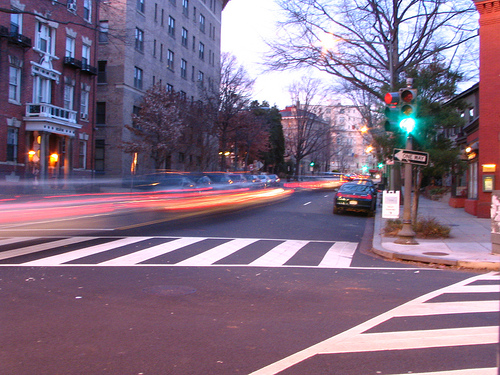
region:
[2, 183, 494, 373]
paved street with thick white stripes at crosswalks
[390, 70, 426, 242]
pole with traffic sign and green traffic signal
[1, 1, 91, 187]
brick building with columns and terrace over entry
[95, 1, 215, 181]
flowering tree in front of plain brick apartment building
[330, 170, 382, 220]
black car parked by a curb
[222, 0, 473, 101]
clear sky in back of tree without branches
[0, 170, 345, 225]
cars zooming down street leaving flashes of red and yellow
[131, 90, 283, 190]
cars parked in front of trees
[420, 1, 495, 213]
storefronts with tall building at corner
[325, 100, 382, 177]
lights twinkling in front of tall building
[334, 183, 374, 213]
A car on the side of the road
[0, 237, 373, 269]
Zebra crossing at the corner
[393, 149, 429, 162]
A black and white sign board giving direction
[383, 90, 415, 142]
Traffic signal looking bright green because of long exposure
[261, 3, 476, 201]
A leafless tree against a bright sky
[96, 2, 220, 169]
A brown building by roadside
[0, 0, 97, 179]
A red building by the roadside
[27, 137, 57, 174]
Lights outside a building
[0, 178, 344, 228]
Streak of light of the rear lights of cars on road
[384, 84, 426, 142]
traffic signal with metal pole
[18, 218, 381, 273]
pedestrian crossing on the road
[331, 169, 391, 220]
red color car running on the road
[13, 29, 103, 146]
big building near the road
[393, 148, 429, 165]
street board in the metal pole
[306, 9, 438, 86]
trees with its branches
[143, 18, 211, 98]
windows in the building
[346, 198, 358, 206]
number plate in the car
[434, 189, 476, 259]
side walk with concrete floor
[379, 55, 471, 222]
a light on a pole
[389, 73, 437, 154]
a light on a metal pole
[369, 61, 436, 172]
a pole with a light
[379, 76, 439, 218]
a metal pole with light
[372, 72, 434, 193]
traffic light on a metal pole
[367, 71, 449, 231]
metal pole with traffic light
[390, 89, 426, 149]
traffic light is green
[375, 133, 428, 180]
black and white sign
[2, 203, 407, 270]
white crosswalk on road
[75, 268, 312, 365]
road is dark grey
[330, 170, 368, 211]
green car on curb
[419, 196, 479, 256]
sidewalk is light grey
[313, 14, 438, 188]
bare trees near car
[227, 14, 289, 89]
white and grey sky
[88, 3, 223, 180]
light brown building across street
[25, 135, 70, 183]
orange lights on building